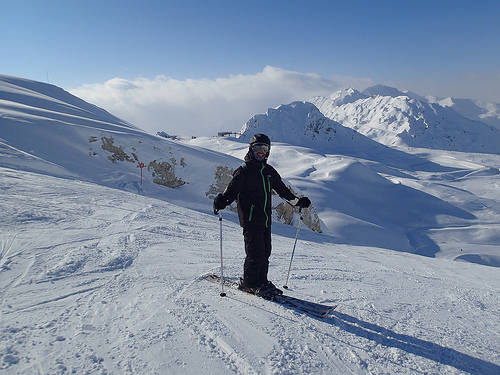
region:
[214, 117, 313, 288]
this is a man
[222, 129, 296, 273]
the man is posing for a photo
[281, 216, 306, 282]
he is holding a stick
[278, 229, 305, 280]
the stick is thin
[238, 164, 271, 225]
the jacket is black in color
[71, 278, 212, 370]
the place is full of snow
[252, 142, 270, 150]
he is wearing goggles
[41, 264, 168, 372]
the snow is white in color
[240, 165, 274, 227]
the jacket is warm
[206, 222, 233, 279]
the stick is thin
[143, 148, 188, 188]
the surface has no snow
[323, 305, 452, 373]
shadows are on the ground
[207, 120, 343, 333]
the guy is holding skipoles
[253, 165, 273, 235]
the strip is blue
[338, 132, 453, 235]
shadows are on the hill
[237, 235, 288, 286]
the pants are black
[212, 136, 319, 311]
the guy has googles on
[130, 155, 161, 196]
orange pole is on the ground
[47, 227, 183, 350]
skitracks are on the ground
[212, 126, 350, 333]
the guy is smiling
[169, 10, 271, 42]
this is the sky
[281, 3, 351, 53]
the sky is blue in color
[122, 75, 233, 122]
these are some clouds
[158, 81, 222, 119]
the clouds are white in color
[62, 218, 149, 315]
this is the ground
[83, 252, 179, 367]
the ground is full of snow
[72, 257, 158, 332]
the snow is white in color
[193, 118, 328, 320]
the person is snowsurfing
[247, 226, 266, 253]
the suit is black in color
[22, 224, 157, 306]
these are some tracks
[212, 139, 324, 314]
the man is loking at the camera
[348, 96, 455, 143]
the hill is covered with snow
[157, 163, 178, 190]
the surface has no snow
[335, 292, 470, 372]
shadows are on the ground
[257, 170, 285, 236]
the strip is blue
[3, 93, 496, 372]
the weather is cold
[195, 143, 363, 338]
the man is holding two ski poles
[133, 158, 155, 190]
the pole is on the snow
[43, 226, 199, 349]
ski trails are in the snow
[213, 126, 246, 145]
a structure is in the background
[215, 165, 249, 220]
Hand of a person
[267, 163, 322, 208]
Hand of a person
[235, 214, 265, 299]
Leg of a person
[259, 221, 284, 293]
Leg of a person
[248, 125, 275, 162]
Head of a person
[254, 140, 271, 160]
Face of a person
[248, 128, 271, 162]
Head protective gear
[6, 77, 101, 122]
This is a hill of snow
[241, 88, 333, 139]
This is a hill of snow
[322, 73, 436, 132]
This is a hill of snow